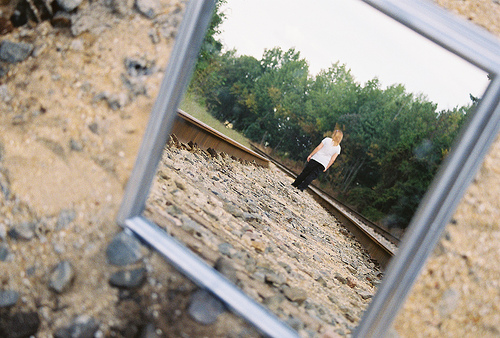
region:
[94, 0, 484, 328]
a mirror on the ground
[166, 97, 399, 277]
a reflection of train tracks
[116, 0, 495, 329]
a gray frame on a mirror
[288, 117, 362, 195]
a reflection of a woman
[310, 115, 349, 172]
a white shirt on a woman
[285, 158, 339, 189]
black pants on a woman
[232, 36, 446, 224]
trees along train tracks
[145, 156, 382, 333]
rocks along the tracks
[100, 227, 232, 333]
rocks in front of a mirror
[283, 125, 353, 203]
a woman standing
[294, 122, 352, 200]
the women on the train tracks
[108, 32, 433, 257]
a lady on a train track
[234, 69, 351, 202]
this photo is so weird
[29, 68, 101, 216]
rocks on the ground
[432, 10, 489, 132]
some sort of mirror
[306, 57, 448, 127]
trees in the reflection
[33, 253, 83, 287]
dirt on the ground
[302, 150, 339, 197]
the black pants of the girl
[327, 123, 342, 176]
the white shirt of the girl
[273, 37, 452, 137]
the trees in the reflection if it is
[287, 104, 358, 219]
the reflection of a woman on train tracks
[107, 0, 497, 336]
a mirror with a silver frame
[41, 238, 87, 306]
a small rock embedded in the dirt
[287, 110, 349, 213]
a woman wearing a white shirt and black pants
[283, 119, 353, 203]
a woman with blonde hair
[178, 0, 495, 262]
trees that are reflected in the mirror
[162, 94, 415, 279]
railroad tracks leading through trees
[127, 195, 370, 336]
wooden railroad ties in a mirror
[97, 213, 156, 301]
two rocks near the mirror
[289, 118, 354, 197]
a woman facing away from the camera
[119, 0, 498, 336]
mirror laying on ground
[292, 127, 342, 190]
woman wearing black pants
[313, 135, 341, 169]
woman wearing white shirt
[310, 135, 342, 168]
shirt is short sleeve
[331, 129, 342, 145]
woman has blond hair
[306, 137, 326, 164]
woman's arms are at her sides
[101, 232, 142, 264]
rocks on the ground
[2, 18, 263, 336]
the ground is rocky and brown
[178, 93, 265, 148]
grass next to railroad track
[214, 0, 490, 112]
sky is gray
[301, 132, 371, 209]
Person wearing white shirt.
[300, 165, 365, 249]
Person wearing black pants.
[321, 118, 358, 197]
Person with blonde hair.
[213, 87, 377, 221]
Person walking in railroad tracks.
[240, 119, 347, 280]
Reflection of person in mirror.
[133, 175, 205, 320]
Mirror has silver frame.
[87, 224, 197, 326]
Gray rocks near frame.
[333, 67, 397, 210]
Green leaves on trees.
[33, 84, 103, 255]
Ground is dirt and rocks.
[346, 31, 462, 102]
Sky is light and clear.